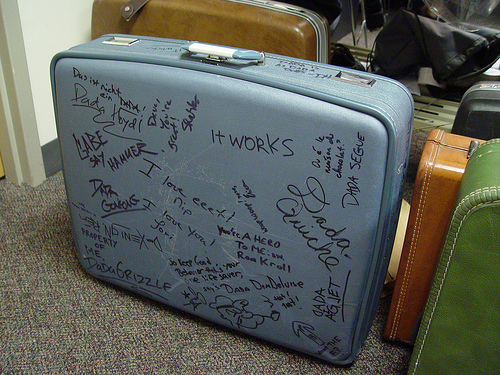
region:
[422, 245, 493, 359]
Green suitcase sitting on ground.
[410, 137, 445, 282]
Brown suitcase sitting on ground.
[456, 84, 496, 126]
Black suitcase sitting on ground.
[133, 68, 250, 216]
Blue suitcase sitting on ground.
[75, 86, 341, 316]
Black writing on suitcase.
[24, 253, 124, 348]
Gray carpet covering the ground.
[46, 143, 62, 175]
Gray baseboards in room.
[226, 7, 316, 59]
Brown suitcase behind blue suitcase.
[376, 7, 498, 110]
Black bag behind suitcases.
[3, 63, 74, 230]
Gray door frame in room.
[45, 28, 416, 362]
This is a bag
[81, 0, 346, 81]
This is a bag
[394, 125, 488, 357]
This is a bag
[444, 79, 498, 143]
This is a bag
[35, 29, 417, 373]
This is a briefcase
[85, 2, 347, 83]
This is a briefcase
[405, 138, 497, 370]
This is a briefcase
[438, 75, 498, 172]
This is a briefcase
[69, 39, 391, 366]
Gray colored suitcase with writing.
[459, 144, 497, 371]
Green colored suitcase with white stitching.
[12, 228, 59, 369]
Gray and white tweed floor rug.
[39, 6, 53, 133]
Wall painted bright white.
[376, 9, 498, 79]
Black jacket sleeve on luggage.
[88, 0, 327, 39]
Brown and metal type luggage.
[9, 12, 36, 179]
Gray wooden door trim.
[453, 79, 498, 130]
Blackish colored luggage trimmed in metal.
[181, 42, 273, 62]
White and blue luggage handle.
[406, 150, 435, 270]
White stitching on brown luggage.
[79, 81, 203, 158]
black marker writing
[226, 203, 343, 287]
black signatures on a suitcase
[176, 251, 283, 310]
black writing on a suitcase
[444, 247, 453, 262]
white thread in a seam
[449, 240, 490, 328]
green leather on a suitcase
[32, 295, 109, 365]
rough gray carpet on the floor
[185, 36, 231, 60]
white tag on the handle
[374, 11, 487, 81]
black nylon bag on the floor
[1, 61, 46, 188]
white wooden door frame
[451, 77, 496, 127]
the corner of a black suitcase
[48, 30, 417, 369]
blue suitcase with writing on it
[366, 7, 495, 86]
black softcover bag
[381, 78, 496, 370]
three suitcases lined up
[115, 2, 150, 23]
brown strap hanging over suitcase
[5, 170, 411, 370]
thin blue carpet on floor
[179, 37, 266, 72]
blue and white suitcase handle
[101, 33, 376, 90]
two silver locks on top of suitcase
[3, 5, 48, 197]
bottom of white door frame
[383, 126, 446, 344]
thick white stitching on edge of luggage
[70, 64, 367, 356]
writing all over side of suitcase